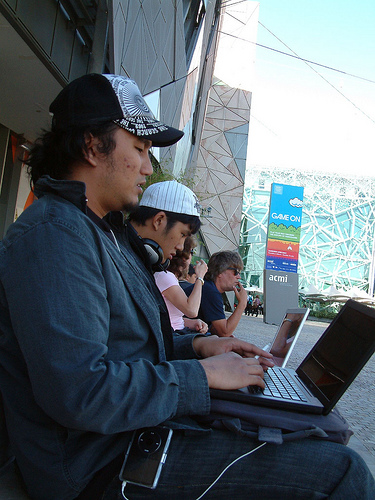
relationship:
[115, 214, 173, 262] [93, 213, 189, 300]
headphone on neck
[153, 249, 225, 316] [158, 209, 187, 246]
man with face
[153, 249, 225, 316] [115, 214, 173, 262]
man has headphone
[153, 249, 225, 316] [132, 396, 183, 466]
man has ipod